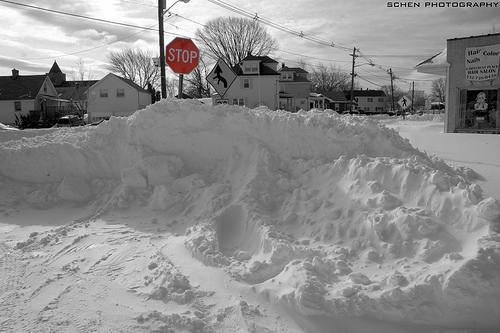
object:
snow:
[0, 97, 499, 331]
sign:
[396, 95, 414, 111]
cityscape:
[0, 0, 499, 332]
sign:
[202, 57, 237, 99]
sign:
[162, 38, 202, 75]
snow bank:
[0, 95, 498, 333]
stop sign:
[162, 37, 201, 77]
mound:
[0, 86, 418, 202]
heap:
[0, 99, 499, 332]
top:
[163, 36, 199, 46]